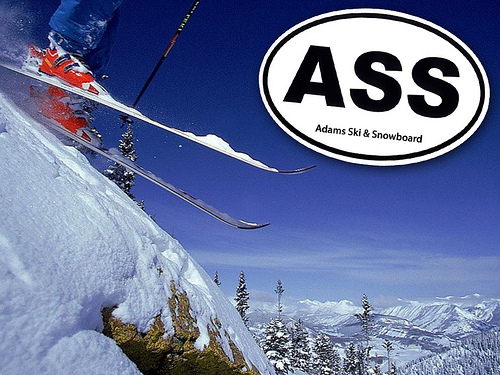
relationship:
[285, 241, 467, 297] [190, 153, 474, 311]
cloud in sky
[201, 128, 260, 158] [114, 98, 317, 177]
snow on ski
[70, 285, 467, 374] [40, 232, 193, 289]
ground has snow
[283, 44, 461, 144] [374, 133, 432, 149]
logo on snowboard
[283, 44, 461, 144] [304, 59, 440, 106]
logo say ass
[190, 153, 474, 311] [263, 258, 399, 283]
sky has clouds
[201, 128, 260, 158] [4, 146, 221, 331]
snow on mountain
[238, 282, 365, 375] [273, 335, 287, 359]
trees has snow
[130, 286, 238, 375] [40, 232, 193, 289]
rock under snow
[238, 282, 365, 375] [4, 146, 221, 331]
trees below mountain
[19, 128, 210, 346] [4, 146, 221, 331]
slope of mountain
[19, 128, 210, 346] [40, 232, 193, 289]
slope has snow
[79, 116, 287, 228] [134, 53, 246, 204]
skis in air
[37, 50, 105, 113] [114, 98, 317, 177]
boots on ski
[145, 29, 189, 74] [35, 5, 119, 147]
ski pole of skier